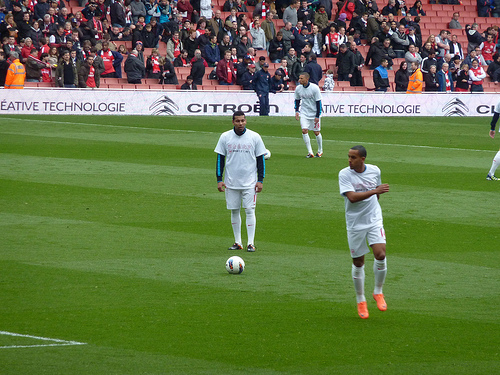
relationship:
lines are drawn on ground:
[3, 324, 90, 360] [1, 114, 497, 373]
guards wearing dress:
[2, 49, 26, 89] [4, 61, 26, 86]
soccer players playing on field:
[212, 73, 397, 318] [0, 115, 499, 373]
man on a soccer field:
[317, 125, 406, 325] [72, 117, 466, 373]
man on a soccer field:
[208, 101, 283, 259] [72, 117, 466, 373]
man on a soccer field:
[284, 60, 330, 169] [72, 117, 466, 373]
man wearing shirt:
[211, 110, 268, 253] [221, 123, 261, 173]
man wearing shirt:
[211, 110, 268, 253] [215, 139, 265, 199]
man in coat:
[3, 52, 24, 84] [2, 60, 31, 89]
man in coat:
[407, 52, 423, 94] [407, 71, 428, 94]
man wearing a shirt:
[317, 125, 406, 221] [338, 163, 385, 209]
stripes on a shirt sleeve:
[213, 150, 230, 180] [207, 145, 237, 185]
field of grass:
[20, 122, 499, 365] [14, 122, 291, 332]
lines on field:
[3, 324, 90, 360] [12, 166, 271, 344]